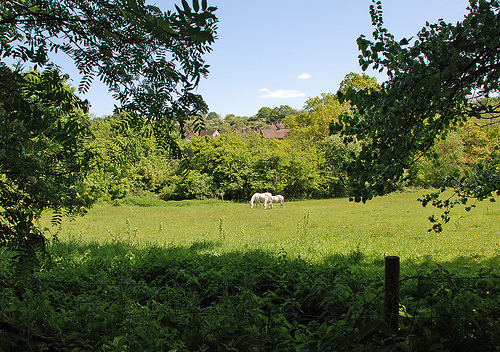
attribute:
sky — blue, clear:
[0, 1, 499, 119]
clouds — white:
[249, 68, 311, 109]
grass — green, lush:
[29, 197, 498, 266]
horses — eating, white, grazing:
[248, 187, 285, 206]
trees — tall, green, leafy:
[2, 0, 500, 257]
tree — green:
[2, 4, 204, 331]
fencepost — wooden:
[384, 253, 403, 333]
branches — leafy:
[337, 7, 499, 230]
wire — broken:
[338, 274, 470, 351]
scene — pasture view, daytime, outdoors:
[1, 0, 493, 350]